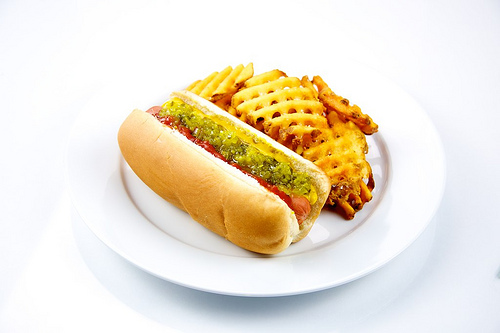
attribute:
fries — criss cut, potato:
[188, 65, 378, 219]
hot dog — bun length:
[149, 105, 311, 223]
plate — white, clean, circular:
[81, 58, 446, 300]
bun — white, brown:
[119, 112, 300, 258]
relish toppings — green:
[182, 117, 288, 187]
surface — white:
[0, 1, 499, 329]